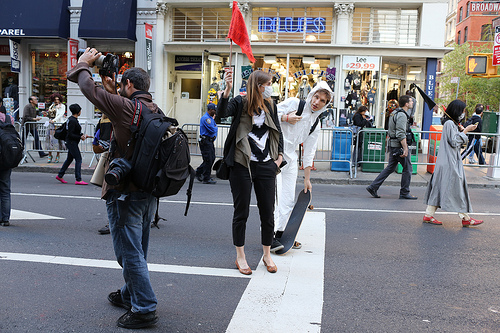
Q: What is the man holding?
A: Camera.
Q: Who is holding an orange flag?
A: The woman.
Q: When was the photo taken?
A: Morning.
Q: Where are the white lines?
A: On the street.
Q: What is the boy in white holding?
A: Skateboard.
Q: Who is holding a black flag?
A: Lady on the right.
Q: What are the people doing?
A: Walking.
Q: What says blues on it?
A: Sign on the building.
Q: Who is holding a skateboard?
A: Man in white.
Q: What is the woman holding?
A: Flag.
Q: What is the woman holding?
A: Flag.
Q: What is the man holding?
A: Bag.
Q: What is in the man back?
A: Bag.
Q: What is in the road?
A: Lines.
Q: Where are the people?
A: In the street.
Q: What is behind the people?
A: A store.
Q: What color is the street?
A: Grey and White.